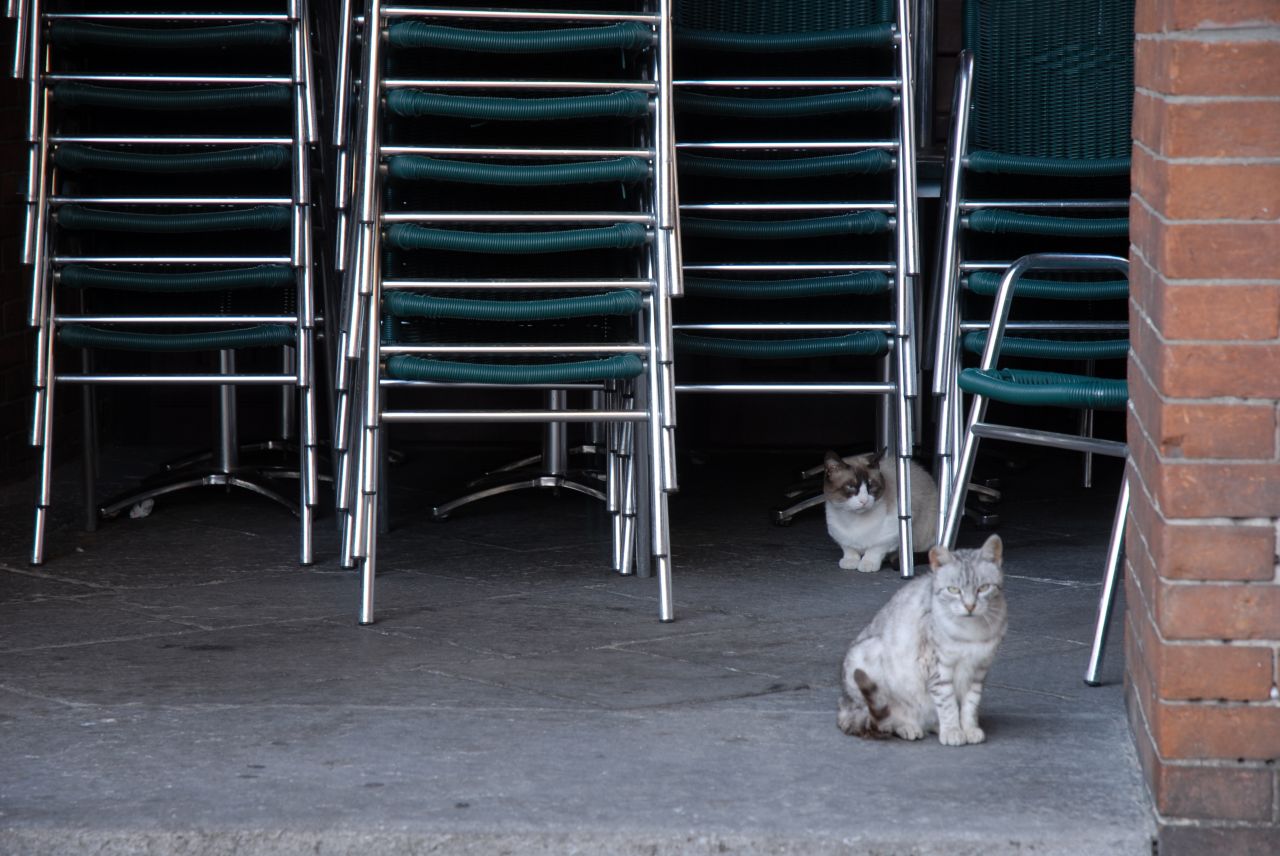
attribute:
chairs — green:
[17, 0, 388, 570]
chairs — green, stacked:
[333, 11, 693, 585]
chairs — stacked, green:
[648, 5, 905, 581]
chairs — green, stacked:
[948, 2, 1134, 539]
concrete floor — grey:
[180, 634, 693, 815]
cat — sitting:
[851, 546, 1021, 727]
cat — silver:
[842, 530, 1010, 740]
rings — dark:
[842, 530, 1010, 740]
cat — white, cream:
[803, 455, 923, 601]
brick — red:
[1134, 2, 1274, 854]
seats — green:
[39, 7, 309, 374]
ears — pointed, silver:
[920, 534, 1005, 568]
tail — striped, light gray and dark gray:
[847, 656, 896, 738]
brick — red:
[1158, 514, 1276, 576]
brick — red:
[1158, 398, 1276, 462]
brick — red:
[1158, 274, 1276, 345]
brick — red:
[1158, 157, 1276, 221]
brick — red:
[1158, 34, 1276, 105]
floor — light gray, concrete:
[15, 407, 1157, 847]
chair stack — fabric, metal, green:
[937, 31, 1129, 564]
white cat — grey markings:
[832, 530, 1014, 756]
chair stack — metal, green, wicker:
[20, 3, 329, 589]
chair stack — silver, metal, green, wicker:
[339, 5, 682, 637]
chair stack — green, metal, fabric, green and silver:
[662, 0, 923, 577]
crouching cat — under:
[816, 448, 949, 577]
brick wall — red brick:
[1123, 9, 1274, 820]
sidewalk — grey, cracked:
[13, 428, 1154, 813]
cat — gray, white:
[832, 534, 1018, 758]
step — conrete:
[4, 760, 1201, 851]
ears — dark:
[817, 448, 887, 481]